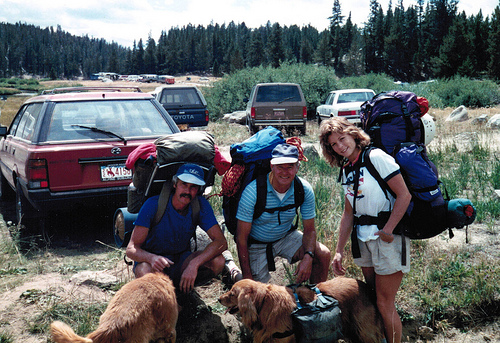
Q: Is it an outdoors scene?
A: Yes, it is outdoors.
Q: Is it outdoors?
A: Yes, it is outdoors.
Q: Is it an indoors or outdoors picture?
A: It is outdoors.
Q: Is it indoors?
A: No, it is outdoors.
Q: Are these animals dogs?
A: Yes, all the animals are dogs.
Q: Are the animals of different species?
A: No, all the animals are dogs.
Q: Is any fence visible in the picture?
A: No, there are no fences.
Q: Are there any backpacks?
A: Yes, there is a backpack.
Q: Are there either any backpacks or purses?
A: Yes, there is a backpack.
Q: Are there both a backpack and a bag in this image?
A: Yes, there are both a backpack and a bag.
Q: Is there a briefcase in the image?
A: No, there are no briefcases.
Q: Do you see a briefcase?
A: No, there are no briefcases.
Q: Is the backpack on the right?
A: Yes, the backpack is on the right of the image.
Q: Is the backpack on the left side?
A: No, the backpack is on the right of the image.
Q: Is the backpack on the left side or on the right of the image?
A: The backpack is on the right of the image.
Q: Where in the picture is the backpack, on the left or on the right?
A: The backpack is on the right of the image.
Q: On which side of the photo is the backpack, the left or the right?
A: The backpack is on the right of the image.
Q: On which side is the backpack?
A: The backpack is on the right of the image.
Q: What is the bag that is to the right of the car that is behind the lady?
A: The bag is a backpack.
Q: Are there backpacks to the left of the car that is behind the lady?
A: No, the backpack is to the right of the car.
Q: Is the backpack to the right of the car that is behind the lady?
A: Yes, the backpack is to the right of the car.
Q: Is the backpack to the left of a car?
A: No, the backpack is to the right of a car.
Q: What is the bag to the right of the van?
A: The bag is a backpack.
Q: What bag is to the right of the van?
A: The bag is a backpack.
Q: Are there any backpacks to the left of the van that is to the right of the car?
A: No, the backpack is to the right of the van.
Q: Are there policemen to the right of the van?
A: No, there is a backpack to the right of the van.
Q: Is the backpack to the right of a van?
A: Yes, the backpack is to the right of a van.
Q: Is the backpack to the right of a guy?
A: No, the backpack is to the right of a van.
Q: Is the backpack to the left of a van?
A: No, the backpack is to the right of a van.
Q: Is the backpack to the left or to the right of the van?
A: The backpack is to the right of the van.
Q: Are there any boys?
A: No, there are no boys.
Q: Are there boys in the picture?
A: No, there are no boys.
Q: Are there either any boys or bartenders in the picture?
A: No, there are no boys or bartenders.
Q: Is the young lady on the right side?
A: Yes, the lady is on the right of the image.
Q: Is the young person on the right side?
A: Yes, the lady is on the right of the image.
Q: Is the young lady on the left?
A: No, the lady is on the right of the image.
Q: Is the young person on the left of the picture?
A: No, the lady is on the right of the image.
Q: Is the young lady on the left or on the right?
A: The lady is on the right of the image.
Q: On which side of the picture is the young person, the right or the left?
A: The lady is on the right of the image.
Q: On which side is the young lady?
A: The lady is on the right of the image.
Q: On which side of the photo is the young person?
A: The lady is on the right of the image.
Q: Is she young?
A: Yes, the lady is young.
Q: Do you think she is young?
A: Yes, the lady is young.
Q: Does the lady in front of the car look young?
A: Yes, the lady is young.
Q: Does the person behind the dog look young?
A: Yes, the lady is young.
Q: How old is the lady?
A: The lady is young.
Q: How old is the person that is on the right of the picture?
A: The lady is young.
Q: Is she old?
A: No, the lady is young.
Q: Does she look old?
A: No, the lady is young.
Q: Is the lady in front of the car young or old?
A: The lady is young.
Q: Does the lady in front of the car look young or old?
A: The lady is young.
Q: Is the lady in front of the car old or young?
A: The lady is young.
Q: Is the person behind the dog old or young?
A: The lady is young.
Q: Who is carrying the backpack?
A: The lady is carrying the backpack.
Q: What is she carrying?
A: The lady is carrying a backpack.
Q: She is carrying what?
A: The lady is carrying a backpack.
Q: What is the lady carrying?
A: The lady is carrying a backpack.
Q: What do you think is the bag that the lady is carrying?
A: The bag is a backpack.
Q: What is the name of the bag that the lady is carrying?
A: The bag is a backpack.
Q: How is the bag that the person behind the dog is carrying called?
A: The bag is a backpack.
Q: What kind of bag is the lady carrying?
A: The lady is carrying a backpack.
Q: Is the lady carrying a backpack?
A: Yes, the lady is carrying a backpack.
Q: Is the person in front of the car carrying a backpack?
A: Yes, the lady is carrying a backpack.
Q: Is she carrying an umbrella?
A: No, the lady is carrying a backpack.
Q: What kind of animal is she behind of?
A: The lady is behind the dog.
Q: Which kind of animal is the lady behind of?
A: The lady is behind the dog.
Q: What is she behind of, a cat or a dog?
A: The lady is behind a dog.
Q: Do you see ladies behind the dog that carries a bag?
A: Yes, there is a lady behind the dog.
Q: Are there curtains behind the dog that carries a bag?
A: No, there is a lady behind the dog.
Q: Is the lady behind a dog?
A: Yes, the lady is behind a dog.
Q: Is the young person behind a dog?
A: Yes, the lady is behind a dog.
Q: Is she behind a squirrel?
A: No, the lady is behind a dog.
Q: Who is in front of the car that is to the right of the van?
A: The lady is in front of the car.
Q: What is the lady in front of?
A: The lady is in front of the car.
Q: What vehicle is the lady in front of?
A: The lady is in front of the car.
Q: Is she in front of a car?
A: Yes, the lady is in front of a car.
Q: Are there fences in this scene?
A: No, there are no fences.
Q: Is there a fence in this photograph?
A: No, there are no fences.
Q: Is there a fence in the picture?
A: No, there are no fences.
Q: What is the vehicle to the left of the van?
A: The vehicle is a car.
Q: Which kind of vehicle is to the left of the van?
A: The vehicle is a car.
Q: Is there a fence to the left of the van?
A: No, there is a car to the left of the van.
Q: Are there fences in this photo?
A: No, there are no fences.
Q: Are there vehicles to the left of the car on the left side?
A: No, the vehicles are to the right of the car.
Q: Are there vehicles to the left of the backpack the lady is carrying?
A: Yes, there are vehicles to the left of the backpack.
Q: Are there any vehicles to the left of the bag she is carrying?
A: Yes, there are vehicles to the left of the backpack.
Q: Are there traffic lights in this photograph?
A: No, there are no traffic lights.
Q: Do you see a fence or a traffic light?
A: No, there are no traffic lights or fences.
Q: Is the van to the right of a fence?
A: No, the van is to the right of a car.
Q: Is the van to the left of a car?
A: No, the van is to the right of a car.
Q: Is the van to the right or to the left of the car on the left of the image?
A: The van is to the right of the car.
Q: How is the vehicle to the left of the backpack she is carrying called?
A: The vehicle is a van.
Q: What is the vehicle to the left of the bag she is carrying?
A: The vehicle is a van.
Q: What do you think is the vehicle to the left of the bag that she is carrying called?
A: The vehicle is a van.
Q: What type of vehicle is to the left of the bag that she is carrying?
A: The vehicle is a van.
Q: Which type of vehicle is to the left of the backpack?
A: The vehicle is a van.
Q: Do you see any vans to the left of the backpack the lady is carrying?
A: Yes, there is a van to the left of the backpack.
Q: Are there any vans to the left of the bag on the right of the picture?
A: Yes, there is a van to the left of the backpack.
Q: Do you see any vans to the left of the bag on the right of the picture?
A: Yes, there is a van to the left of the backpack.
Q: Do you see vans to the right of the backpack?
A: No, the van is to the left of the backpack.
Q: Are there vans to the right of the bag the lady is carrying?
A: No, the van is to the left of the backpack.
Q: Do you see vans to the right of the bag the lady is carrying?
A: No, the van is to the left of the backpack.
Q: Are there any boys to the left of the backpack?
A: No, there is a van to the left of the backpack.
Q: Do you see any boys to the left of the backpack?
A: No, there is a van to the left of the backpack.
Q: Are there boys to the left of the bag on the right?
A: No, there is a van to the left of the backpack.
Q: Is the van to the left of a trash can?
A: No, the van is to the left of the backpack.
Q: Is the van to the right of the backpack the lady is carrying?
A: No, the van is to the left of the backpack.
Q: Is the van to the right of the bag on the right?
A: No, the van is to the left of the backpack.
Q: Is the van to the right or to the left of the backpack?
A: The van is to the left of the backpack.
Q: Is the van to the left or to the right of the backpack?
A: The van is to the left of the backpack.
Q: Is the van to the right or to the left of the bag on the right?
A: The van is to the left of the backpack.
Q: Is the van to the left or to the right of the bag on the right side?
A: The van is to the left of the backpack.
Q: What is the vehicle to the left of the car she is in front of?
A: The vehicle is a van.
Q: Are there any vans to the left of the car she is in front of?
A: Yes, there is a van to the left of the car.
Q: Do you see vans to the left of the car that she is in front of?
A: Yes, there is a van to the left of the car.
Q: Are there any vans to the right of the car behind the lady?
A: No, the van is to the left of the car.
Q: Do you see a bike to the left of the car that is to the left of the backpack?
A: No, there is a van to the left of the car.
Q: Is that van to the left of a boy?
A: No, the van is to the left of a car.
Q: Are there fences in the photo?
A: No, there are no fences.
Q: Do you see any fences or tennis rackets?
A: No, there are no fences or tennis rackets.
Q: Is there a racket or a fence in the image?
A: No, there are no fences or rackets.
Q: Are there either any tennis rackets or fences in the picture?
A: No, there are no fences or tennis rackets.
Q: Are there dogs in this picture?
A: Yes, there is a dog.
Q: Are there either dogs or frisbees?
A: Yes, there is a dog.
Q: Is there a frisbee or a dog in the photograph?
A: Yes, there is a dog.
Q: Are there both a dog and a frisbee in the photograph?
A: No, there is a dog but no frisbees.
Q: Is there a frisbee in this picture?
A: No, there are no frisbees.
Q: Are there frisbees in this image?
A: No, there are no frisbees.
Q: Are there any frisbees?
A: No, there are no frisbees.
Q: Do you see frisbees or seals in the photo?
A: No, there are no frisbees or seals.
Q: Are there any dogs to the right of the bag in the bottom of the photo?
A: No, the dog is to the left of the bag.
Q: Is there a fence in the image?
A: No, there are no fences.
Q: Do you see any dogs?
A: Yes, there is a dog.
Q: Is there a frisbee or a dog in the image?
A: Yes, there is a dog.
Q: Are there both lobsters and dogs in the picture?
A: No, there is a dog but no lobsters.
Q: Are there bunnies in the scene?
A: No, there are no bunnies.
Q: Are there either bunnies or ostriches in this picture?
A: No, there are no bunnies or ostriches.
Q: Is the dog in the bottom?
A: Yes, the dog is in the bottom of the image.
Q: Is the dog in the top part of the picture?
A: No, the dog is in the bottom of the image.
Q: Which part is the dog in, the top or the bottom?
A: The dog is in the bottom of the image.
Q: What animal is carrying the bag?
A: The dog is carrying the bag.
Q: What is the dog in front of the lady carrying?
A: The dog is carrying a bag.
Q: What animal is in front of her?
A: The dog is in front of the lady.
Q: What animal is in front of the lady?
A: The dog is in front of the lady.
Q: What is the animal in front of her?
A: The animal is a dog.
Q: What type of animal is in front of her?
A: The animal is a dog.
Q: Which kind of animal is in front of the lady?
A: The animal is a dog.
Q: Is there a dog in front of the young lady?
A: Yes, there is a dog in front of the lady.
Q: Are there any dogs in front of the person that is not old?
A: Yes, there is a dog in front of the lady.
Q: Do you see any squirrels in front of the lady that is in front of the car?
A: No, there is a dog in front of the lady.